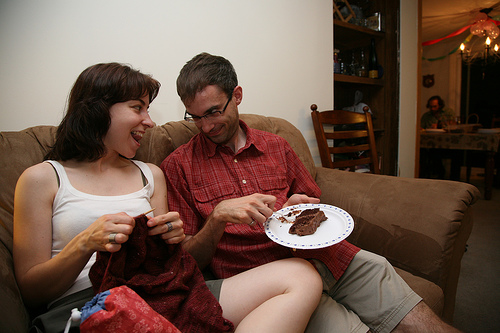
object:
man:
[158, 52, 460, 331]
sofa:
[3, 114, 479, 330]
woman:
[14, 63, 323, 333]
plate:
[264, 203, 355, 250]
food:
[289, 208, 329, 237]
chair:
[309, 103, 469, 254]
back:
[310, 103, 380, 173]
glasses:
[184, 94, 233, 121]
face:
[187, 91, 238, 142]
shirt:
[160, 119, 362, 282]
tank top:
[42, 159, 157, 306]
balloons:
[481, 18, 500, 30]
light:
[460, 42, 465, 52]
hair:
[40, 62, 162, 164]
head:
[57, 63, 153, 159]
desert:
[296, 224, 316, 236]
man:
[421, 96, 451, 129]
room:
[422, 1, 496, 197]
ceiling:
[422, 2, 499, 29]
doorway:
[413, 0, 499, 188]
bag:
[67, 285, 183, 332]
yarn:
[97, 244, 112, 293]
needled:
[133, 208, 157, 219]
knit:
[87, 208, 204, 282]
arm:
[317, 166, 482, 276]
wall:
[2, 0, 336, 164]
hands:
[81, 212, 134, 254]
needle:
[130, 207, 156, 219]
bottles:
[357, 51, 369, 77]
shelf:
[336, 1, 400, 176]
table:
[420, 127, 500, 194]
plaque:
[422, 74, 435, 89]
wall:
[423, 35, 463, 129]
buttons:
[242, 179, 247, 184]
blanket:
[81, 285, 181, 332]